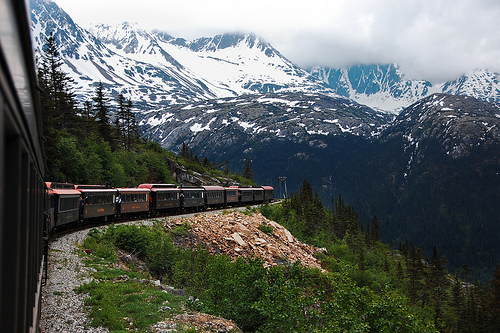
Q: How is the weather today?
A: It is cloudy.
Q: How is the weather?
A: It is cloudy.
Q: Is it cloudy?
A: Yes, it is cloudy.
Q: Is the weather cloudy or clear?
A: It is cloudy.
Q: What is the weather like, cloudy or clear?
A: It is cloudy.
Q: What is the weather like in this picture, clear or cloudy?
A: It is cloudy.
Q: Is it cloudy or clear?
A: It is cloudy.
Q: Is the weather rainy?
A: No, it is cloudy.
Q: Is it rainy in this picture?
A: No, it is cloudy.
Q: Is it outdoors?
A: Yes, it is outdoors.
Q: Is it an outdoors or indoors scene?
A: It is outdoors.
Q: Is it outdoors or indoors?
A: It is outdoors.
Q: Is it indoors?
A: No, it is outdoors.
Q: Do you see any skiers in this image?
A: No, there are no skiers.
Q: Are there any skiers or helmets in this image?
A: No, there are no skiers or helmets.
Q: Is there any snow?
A: Yes, there is snow.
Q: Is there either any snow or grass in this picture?
A: Yes, there is snow.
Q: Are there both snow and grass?
A: Yes, there are both snow and grass.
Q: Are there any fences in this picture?
A: No, there are no fences.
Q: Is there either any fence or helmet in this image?
A: No, there are no fences or helmets.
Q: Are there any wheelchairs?
A: No, there are no wheelchairs.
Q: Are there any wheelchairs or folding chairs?
A: No, there are no wheelchairs or folding chairs.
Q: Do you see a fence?
A: No, there are no fences.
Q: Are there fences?
A: No, there are no fences.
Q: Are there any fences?
A: No, there are no fences.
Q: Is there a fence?
A: No, there are no fences.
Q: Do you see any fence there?
A: No, there are no fences.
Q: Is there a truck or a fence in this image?
A: No, there are no fences or trucks.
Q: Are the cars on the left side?
A: Yes, the cars are on the left of the image.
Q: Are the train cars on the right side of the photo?
A: No, the cars are on the left of the image.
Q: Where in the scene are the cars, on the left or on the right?
A: The cars are on the left of the image.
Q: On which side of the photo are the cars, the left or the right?
A: The cars are on the left of the image.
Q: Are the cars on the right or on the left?
A: The cars are on the left of the image.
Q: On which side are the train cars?
A: The cars are on the left of the image.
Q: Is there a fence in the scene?
A: No, there are no fences.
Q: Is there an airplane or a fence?
A: No, there are no fences or airplanes.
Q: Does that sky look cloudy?
A: Yes, the sky is cloudy.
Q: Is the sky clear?
A: No, the sky is cloudy.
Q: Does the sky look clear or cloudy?
A: The sky is cloudy.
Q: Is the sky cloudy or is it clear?
A: The sky is cloudy.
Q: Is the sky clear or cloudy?
A: The sky is cloudy.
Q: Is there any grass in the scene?
A: Yes, there is grass.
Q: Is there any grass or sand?
A: Yes, there is grass.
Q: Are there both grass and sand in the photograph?
A: No, there is grass but no sand.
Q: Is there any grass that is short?
A: Yes, there is short grass.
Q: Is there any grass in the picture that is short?
A: Yes, there is grass that is short.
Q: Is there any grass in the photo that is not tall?
A: Yes, there is short grass.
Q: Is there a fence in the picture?
A: No, there are no fences.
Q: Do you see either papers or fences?
A: No, there are no fences or papers.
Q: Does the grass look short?
A: Yes, the grass is short.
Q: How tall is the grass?
A: The grass is short.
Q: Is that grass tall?
A: No, the grass is short.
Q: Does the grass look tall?
A: No, the grass is short.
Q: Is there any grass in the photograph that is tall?
A: No, there is grass but it is short.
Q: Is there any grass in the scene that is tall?
A: No, there is grass but it is short.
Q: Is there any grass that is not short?
A: No, there is grass but it is short.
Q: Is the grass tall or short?
A: The grass is short.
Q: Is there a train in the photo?
A: Yes, there is a train.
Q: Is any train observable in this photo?
A: Yes, there is a train.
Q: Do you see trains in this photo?
A: Yes, there is a train.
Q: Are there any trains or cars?
A: Yes, there is a train.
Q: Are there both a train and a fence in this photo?
A: No, there is a train but no fences.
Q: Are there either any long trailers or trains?
A: Yes, there is a long train.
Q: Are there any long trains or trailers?
A: Yes, there is a long train.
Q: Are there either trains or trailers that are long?
A: Yes, the train is long.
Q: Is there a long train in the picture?
A: Yes, there is a long train.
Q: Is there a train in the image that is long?
A: Yes, there is a train that is long.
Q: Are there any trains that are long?
A: Yes, there is a train that is long.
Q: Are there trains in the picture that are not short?
A: Yes, there is a long train.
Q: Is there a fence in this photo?
A: No, there are no fences.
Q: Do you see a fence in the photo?
A: No, there are no fences.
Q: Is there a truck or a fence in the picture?
A: No, there are no fences or trucks.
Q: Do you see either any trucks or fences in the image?
A: No, there are no fences or trucks.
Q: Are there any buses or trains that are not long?
A: No, there is a train but it is long.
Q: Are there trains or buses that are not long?
A: No, there is a train but it is long.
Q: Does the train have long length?
A: Yes, the train is long.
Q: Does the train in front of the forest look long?
A: Yes, the train is long.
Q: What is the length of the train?
A: The train is long.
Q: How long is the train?
A: The train is long.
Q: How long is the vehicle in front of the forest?
A: The train is long.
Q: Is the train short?
A: No, the train is long.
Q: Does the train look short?
A: No, the train is long.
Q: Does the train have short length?
A: No, the train is long.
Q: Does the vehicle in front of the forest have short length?
A: No, the train is long.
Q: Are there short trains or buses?
A: No, there is a train but it is long.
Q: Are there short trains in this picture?
A: No, there is a train but it is long.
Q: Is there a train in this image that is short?
A: No, there is a train but it is long.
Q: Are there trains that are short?
A: No, there is a train but it is long.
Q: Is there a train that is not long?
A: No, there is a train but it is long.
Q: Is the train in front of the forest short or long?
A: The train is long.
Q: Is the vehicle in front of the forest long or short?
A: The train is long.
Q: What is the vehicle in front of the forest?
A: The vehicle is a train.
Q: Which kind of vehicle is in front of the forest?
A: The vehicle is a train.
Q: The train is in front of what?
A: The train is in front of the forest.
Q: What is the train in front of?
A: The train is in front of the forest.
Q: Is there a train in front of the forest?
A: Yes, there is a train in front of the forest.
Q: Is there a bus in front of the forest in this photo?
A: No, there is a train in front of the forest.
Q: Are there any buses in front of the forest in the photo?
A: No, there is a train in front of the forest.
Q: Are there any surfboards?
A: No, there are no surfboards.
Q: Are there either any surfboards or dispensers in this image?
A: No, there are no surfboards or dispensers.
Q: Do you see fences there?
A: No, there are no fences.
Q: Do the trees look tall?
A: Yes, the trees are tall.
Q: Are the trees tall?
A: Yes, the trees are tall.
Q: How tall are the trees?
A: The trees are tall.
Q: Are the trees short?
A: No, the trees are tall.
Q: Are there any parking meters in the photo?
A: No, there are no parking meters.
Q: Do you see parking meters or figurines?
A: No, there are no parking meters or figurines.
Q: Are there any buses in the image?
A: No, there are no buses.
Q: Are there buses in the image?
A: No, there are no buses.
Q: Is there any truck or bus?
A: No, there are no buses or trucks.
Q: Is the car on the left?
A: Yes, the car is on the left of the image.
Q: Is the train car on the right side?
A: No, the car is on the left of the image.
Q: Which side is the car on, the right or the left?
A: The car is on the left of the image.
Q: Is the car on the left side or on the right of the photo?
A: The car is on the left of the image.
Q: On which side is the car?
A: The car is on the left of the image.